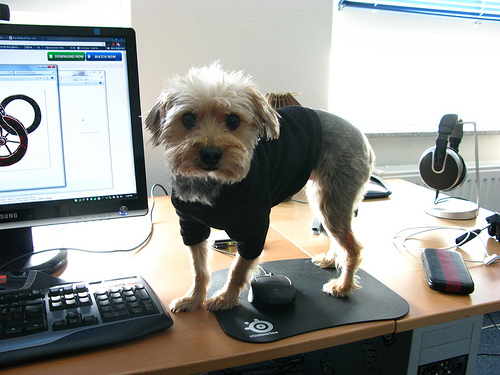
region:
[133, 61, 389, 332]
A brown and grey dog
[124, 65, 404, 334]
A dog in a black shirt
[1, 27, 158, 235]
A lit up computer screen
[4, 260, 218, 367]
A black keyboard on a desk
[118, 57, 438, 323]
A dog on top of a desk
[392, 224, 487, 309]
Red and black striped phone case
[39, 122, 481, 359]
Brown and grey desk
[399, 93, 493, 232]
Black and gray headphones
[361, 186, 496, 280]
Long white cord wrapped up on a desk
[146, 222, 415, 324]
Black computer mouse on a black mouse pad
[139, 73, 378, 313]
small dog wearing black shirt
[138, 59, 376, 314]
small dog standing on desk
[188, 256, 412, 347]
black mouse pad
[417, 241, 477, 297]
black cell phone case with maroon stripe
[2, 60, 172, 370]
black desktop computer on desk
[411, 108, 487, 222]
black and silver headphones on headphone stand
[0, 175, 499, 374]
large wooden desk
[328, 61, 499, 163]
white window with daylight coming through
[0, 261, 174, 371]
black computer keyboard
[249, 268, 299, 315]
black computer mouse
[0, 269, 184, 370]
Black computer keyboard on desk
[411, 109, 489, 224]
Black and silver headphones on stand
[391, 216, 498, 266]
White power cord rolled up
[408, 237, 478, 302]
Black and Red case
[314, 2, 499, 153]
Large window with raised blinds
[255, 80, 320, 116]
Top of lampshade behind dog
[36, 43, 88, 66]
Green download now button on computer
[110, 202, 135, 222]
Blue power button for computer screen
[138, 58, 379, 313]
White dog with black shirt on desk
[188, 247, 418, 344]
Black mouse pad with black mouse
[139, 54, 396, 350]
little dog standing on the table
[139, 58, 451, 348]
little dog wearing black sweater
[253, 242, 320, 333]
black mouse on mouse pad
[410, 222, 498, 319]
cellphone case on table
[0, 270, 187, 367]
black keyboard on table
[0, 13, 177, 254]
computer screen on the table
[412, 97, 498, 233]
silver and black headphones on stand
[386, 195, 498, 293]
white cord on table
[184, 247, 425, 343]
black mouse pad on table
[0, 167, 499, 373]
brown wooden desk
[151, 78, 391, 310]
The dog is on the desk.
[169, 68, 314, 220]
The dog is wearing a black sweater.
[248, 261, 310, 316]
The mouse is on the mouse pad.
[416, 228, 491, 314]
The cellphone is sitting on the desk.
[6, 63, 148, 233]
The computer screen is on.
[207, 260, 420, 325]
The mouse and pad is black.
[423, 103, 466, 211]
headphones are on the table.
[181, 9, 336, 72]
The wall is white.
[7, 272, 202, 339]
The keyboard is black.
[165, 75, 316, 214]
The dog is staring at the camera.